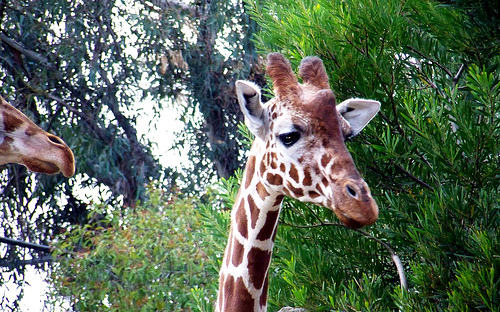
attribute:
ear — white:
[327, 89, 380, 130]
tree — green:
[228, 3, 496, 310]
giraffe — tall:
[212, 47, 379, 309]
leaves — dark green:
[40, 102, 75, 139]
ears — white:
[234, 74, 387, 150]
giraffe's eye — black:
[268, 116, 305, 156]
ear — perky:
[234, 77, 266, 138]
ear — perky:
[337, 96, 382, 140]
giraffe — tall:
[203, 49, 394, 310]